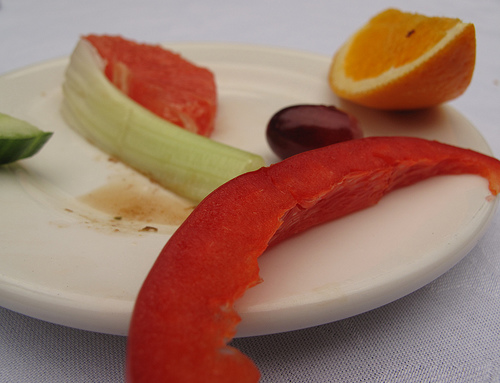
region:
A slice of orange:
[326, 5, 483, 112]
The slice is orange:
[327, 4, 478, 112]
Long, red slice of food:
[124, 124, 491, 376]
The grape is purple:
[263, 97, 360, 154]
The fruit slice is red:
[85, 25, 221, 139]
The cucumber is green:
[1, 103, 51, 163]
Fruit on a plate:
[4, 6, 490, 338]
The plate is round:
[0, 10, 485, 342]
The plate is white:
[0, 39, 488, 336]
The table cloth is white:
[11, 8, 489, 375]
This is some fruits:
[145, 54, 377, 291]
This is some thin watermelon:
[165, 215, 275, 341]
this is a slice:
[143, 31, 214, 86]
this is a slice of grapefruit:
[126, 30, 166, 97]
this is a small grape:
[278, 93, 337, 173]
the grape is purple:
[294, 100, 324, 142]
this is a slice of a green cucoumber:
[10, 104, 65, 169]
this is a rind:
[323, 56, 446, 103]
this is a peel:
[367, 62, 379, 84]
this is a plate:
[18, 214, 127, 278]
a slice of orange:
[319, 6, 476, 120]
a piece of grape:
[244, 89, 366, 153]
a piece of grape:
[238, 93, 397, 190]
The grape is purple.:
[266, 103, 361, 164]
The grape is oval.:
[268, 106, 360, 160]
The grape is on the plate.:
[267, 101, 364, 157]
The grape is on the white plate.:
[264, 101, 362, 154]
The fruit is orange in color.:
[323, 6, 486, 113]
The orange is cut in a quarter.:
[328, 8, 475, 121]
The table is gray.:
[355, 331, 462, 381]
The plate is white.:
[307, 243, 372, 300]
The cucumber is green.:
[1, 104, 53, 164]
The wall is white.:
[16, 11, 61, 51]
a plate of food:
[11, 13, 488, 351]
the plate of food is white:
[1, 38, 476, 330]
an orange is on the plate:
[326, 2, 473, 112]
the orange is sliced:
[329, 10, 473, 99]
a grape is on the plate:
[258, 82, 352, 152]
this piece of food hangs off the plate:
[111, 283, 270, 380]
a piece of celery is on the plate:
[61, 43, 273, 210]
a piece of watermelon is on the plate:
[2, 116, 58, 169]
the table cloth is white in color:
[264, 5, 496, 374]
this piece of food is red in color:
[93, 131, 489, 344]